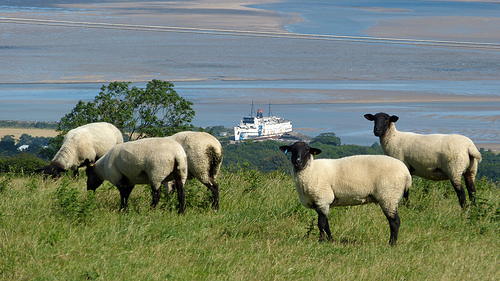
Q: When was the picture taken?
A: Daytime.